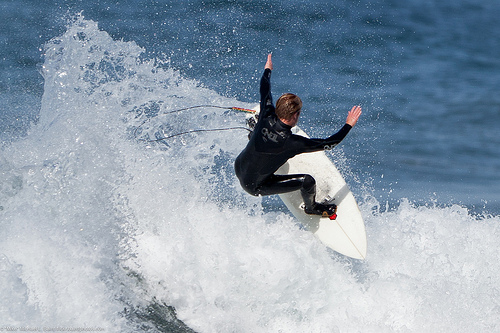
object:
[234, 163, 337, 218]
pants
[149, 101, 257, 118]
cables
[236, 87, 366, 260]
surfboard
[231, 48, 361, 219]
man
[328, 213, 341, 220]
red spot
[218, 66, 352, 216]
wetsuit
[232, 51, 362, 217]
bend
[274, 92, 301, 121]
hair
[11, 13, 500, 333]
splash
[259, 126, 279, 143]
writing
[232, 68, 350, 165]
t-shirt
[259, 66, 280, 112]
man arms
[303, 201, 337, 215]
shoe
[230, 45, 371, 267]
surf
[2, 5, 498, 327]
ocean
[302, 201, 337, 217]
feet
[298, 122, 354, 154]
arms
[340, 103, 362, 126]
hands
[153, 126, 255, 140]
cables